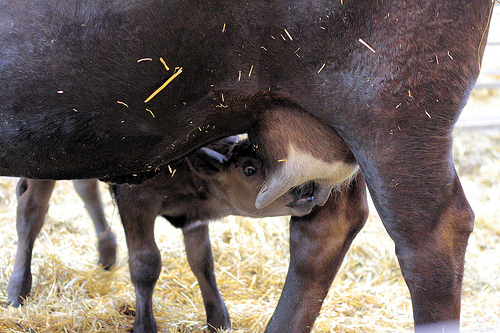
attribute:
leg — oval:
[4, 177, 56, 309]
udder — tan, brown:
[250, 116, 359, 219]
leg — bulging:
[112, 194, 168, 329]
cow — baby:
[13, 90, 378, 331]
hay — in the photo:
[1, 177, 415, 332]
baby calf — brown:
[7, 133, 316, 330]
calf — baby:
[4, 128, 325, 331]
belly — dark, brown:
[4, 21, 240, 183]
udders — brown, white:
[250, 101, 358, 221]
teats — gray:
[250, 172, 332, 208]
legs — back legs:
[6, 177, 116, 306]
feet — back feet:
[260, 108, 474, 331]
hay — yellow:
[112, 35, 198, 110]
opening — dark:
[14, 179, 34, 199]